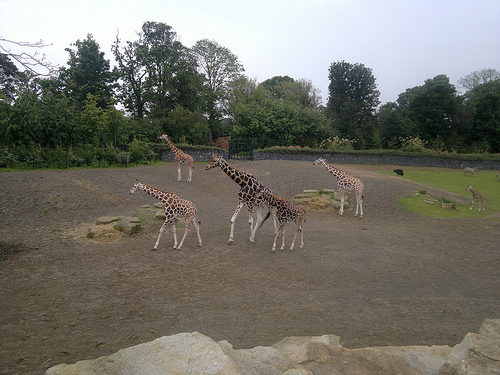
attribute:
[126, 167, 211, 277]
giraffe — one, walking, adult, four, brown, multiple, young, the, white, long, little, mom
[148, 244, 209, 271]
dirt — large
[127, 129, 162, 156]
grass — portion, green, full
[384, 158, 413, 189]
bird — large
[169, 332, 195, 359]
wall — stone, brick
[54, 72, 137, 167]
tree — behind, field, green, tall, line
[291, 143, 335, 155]
fence — black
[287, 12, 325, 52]
sky — blue, cloudy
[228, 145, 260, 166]
gate — black, pen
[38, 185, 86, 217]
outcropping — rock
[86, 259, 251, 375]
field — dirt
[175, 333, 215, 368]
rock — laying, sit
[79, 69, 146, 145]
branch — empty